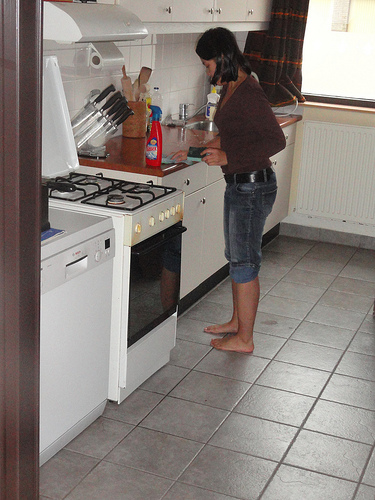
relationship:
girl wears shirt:
[183, 25, 297, 370] [198, 75, 291, 179]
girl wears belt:
[183, 25, 297, 370] [219, 166, 275, 188]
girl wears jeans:
[183, 25, 297, 370] [213, 170, 281, 288]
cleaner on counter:
[140, 101, 167, 173] [76, 104, 309, 175]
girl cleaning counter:
[183, 25, 297, 370] [76, 104, 309, 175]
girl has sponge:
[183, 25, 297, 370] [186, 142, 210, 164]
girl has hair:
[183, 25, 297, 370] [194, 26, 257, 91]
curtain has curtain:
[235, 1, 318, 112] [253, 1, 318, 97]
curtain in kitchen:
[235, 1, 318, 112] [0, 0, 375, 500]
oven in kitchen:
[49, 170, 187, 408] [0, 0, 375, 500]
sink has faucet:
[185, 100, 222, 132] [169, 91, 219, 125]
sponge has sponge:
[186, 142, 210, 164] [186, 142, 210, 164]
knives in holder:
[69, 82, 137, 150] [67, 102, 119, 159]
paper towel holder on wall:
[82, 40, 129, 75] [43, 1, 289, 151]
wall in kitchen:
[43, 1, 289, 151] [0, 0, 375, 500]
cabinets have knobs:
[113, 0, 302, 319] [165, 6, 294, 207]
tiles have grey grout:
[39, 236, 371, 499] [62, 235, 374, 498]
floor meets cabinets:
[39, 236, 371, 499] [113, 0, 302, 319]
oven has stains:
[49, 170, 187, 408] [131, 206, 187, 244]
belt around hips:
[219, 166, 275, 188] [220, 157, 281, 191]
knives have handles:
[69, 82, 137, 150] [83, 81, 136, 128]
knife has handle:
[69, 80, 118, 125] [99, 95, 123, 112]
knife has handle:
[69, 80, 129, 154] [99, 95, 123, 112]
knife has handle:
[69, 80, 129, 154] [108, 95, 131, 116]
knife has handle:
[69, 80, 129, 154] [116, 112, 134, 122]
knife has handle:
[69, 80, 129, 154] [116, 107, 137, 124]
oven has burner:
[49, 170, 187, 408] [82, 188, 148, 213]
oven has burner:
[49, 170, 187, 408] [121, 180, 176, 201]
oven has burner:
[49, 170, 187, 408] [44, 179, 101, 202]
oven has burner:
[49, 170, 187, 408] [75, 169, 124, 191]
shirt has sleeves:
[198, 75, 291, 179] [240, 76, 284, 166]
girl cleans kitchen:
[183, 25, 297, 370] [0, 0, 375, 500]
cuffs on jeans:
[224, 257, 264, 285] [213, 170, 281, 288]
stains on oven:
[131, 206, 187, 244] [49, 170, 187, 408]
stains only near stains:
[131, 206, 187, 244] [131, 206, 187, 244]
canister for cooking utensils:
[117, 97, 151, 140] [114, 62, 154, 98]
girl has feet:
[183, 25, 297, 370] [201, 319, 256, 360]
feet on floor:
[201, 319, 256, 360] [39, 236, 371, 499]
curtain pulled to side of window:
[235, 1, 318, 112] [294, 3, 373, 110]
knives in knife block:
[69, 82, 137, 150] [70, 119, 112, 163]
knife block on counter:
[70, 119, 112, 163] [76, 104, 309, 175]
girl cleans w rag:
[183, 25, 297, 370] [161, 148, 196, 166]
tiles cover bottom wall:
[276, 220, 374, 255] [281, 1, 373, 247]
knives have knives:
[69, 82, 137, 150] [69, 82, 137, 150]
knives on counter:
[69, 82, 137, 150] [76, 104, 309, 175]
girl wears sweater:
[183, 25, 297, 370] [216, 76, 291, 177]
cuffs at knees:
[224, 257, 264, 285] [225, 255, 265, 286]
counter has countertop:
[76, 104, 309, 175] [75, 107, 305, 179]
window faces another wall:
[294, 3, 373, 110] [302, 0, 375, 102]